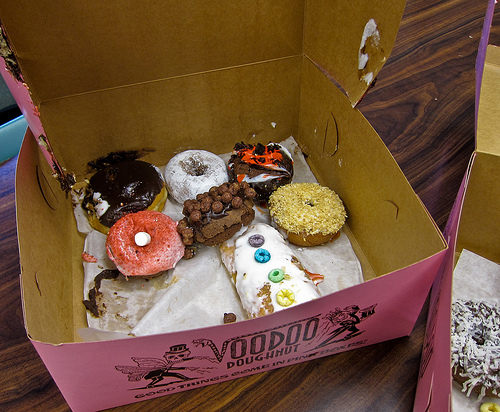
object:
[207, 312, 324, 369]
voodoo doughnut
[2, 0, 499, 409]
table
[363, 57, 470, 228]
ground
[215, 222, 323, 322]
snacks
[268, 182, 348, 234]
icing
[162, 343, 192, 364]
skull people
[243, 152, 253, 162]
orange frosting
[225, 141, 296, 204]
donut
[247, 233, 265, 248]
froot loop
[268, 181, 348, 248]
donut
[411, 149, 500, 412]
pink box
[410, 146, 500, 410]
box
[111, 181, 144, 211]
jam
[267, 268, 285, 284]
froot loop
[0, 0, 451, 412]
box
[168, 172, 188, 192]
ice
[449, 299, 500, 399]
donut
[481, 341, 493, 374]
coconut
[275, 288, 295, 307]
froot loop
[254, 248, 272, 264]
froot loop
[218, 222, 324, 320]
donut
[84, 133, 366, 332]
paper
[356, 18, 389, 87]
icing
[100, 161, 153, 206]
chocolate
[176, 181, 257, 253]
donut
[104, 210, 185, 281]
donut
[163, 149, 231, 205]
donut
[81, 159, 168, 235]
donut